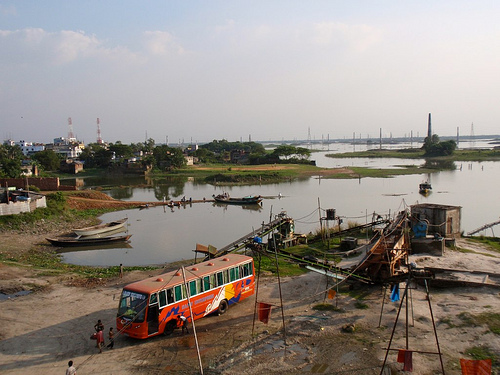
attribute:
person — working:
[177, 311, 191, 331]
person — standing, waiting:
[106, 321, 117, 348]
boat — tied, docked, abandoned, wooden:
[43, 229, 148, 254]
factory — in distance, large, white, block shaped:
[21, 113, 104, 174]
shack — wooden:
[385, 197, 475, 245]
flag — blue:
[389, 278, 405, 300]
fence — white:
[4, 190, 50, 220]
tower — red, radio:
[94, 116, 105, 144]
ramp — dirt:
[67, 185, 186, 209]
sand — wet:
[21, 237, 500, 364]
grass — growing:
[37, 250, 159, 280]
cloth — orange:
[256, 301, 274, 326]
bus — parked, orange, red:
[113, 253, 261, 329]